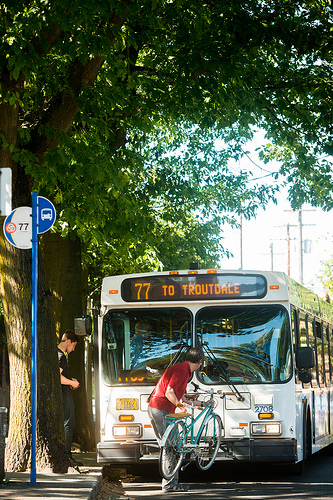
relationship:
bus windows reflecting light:
[112, 306, 270, 376] [217, 324, 252, 352]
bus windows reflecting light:
[101, 304, 293, 389] [217, 324, 252, 352]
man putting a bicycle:
[144, 341, 204, 495] [158, 382, 235, 480]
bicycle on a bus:
[158, 382, 235, 480] [89, 261, 331, 475]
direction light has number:
[115, 268, 268, 302] [113, 273, 161, 309]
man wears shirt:
[50, 327, 100, 467] [54, 346, 74, 402]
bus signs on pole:
[0, 185, 61, 254] [26, 189, 43, 483]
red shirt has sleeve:
[148, 361, 192, 413] [167, 365, 187, 391]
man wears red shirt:
[144, 341, 204, 495] [148, 361, 192, 413]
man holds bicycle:
[147, 346, 206, 493] [157, 394, 227, 475]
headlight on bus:
[108, 423, 142, 441] [89, 261, 331, 475]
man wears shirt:
[56, 327, 82, 468] [143, 354, 214, 406]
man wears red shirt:
[144, 341, 204, 495] [144, 361, 193, 415]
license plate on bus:
[110, 394, 149, 416] [89, 261, 331, 475]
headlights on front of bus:
[249, 421, 282, 436] [89, 261, 331, 475]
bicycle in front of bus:
[158, 381, 224, 479] [89, 261, 331, 475]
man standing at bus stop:
[56, 327, 82, 468] [0, 182, 59, 492]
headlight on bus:
[112, 423, 142, 439] [89, 261, 331, 475]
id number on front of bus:
[254, 403, 272, 413] [89, 261, 331, 475]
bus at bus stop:
[72, 268, 332, 478] [3, 190, 56, 484]